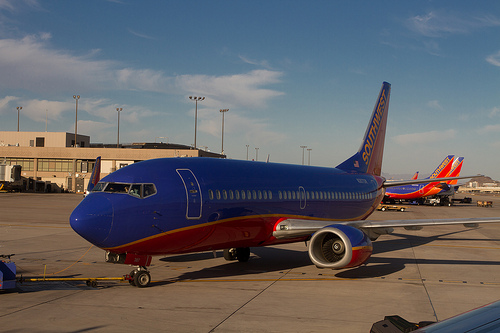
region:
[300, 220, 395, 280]
blue and red jet engine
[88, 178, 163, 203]
cockpit windows on front of plane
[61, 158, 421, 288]
blue and red airplane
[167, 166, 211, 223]
door on side of airplane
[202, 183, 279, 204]
windows on side of airplane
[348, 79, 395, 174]
company logo on airplane tail fin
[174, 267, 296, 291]
yellow stripes on airport runway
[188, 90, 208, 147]
large silver airport light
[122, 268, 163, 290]
landing wheels on airplane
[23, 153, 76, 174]
windows on side of building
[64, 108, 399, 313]
air plane is blue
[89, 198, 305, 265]
red trim of air plane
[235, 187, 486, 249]
silver wing of air plane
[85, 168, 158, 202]
window of air plane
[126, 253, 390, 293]
white line on pavement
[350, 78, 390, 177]
writing on tail of plane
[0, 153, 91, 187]
truck parked by building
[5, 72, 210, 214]
building in distance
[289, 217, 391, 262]
engine of airplane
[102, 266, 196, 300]
wheels of a plane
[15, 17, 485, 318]
An airplane waiting on tarmac.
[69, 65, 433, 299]
A red and blue airplane.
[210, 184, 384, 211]
Passenger windows on airplane.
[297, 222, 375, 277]
Left engine on airplane.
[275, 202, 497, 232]
Left wing on airplane.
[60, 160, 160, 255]
The nose of an airplane.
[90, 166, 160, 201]
The windshield on an airplane.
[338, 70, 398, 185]
The tail of an airplane.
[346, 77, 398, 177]
The word SOUTHWEST in gold letters.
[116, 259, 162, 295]
The front wheel of an airplane.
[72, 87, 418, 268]
blue and red plane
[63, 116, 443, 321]
a plane from southwest airlines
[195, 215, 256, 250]
red bottom of plane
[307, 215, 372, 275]
engine of the plane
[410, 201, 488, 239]
silver wing of plane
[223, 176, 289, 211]
windows on the plane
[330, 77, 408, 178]
tail of the plane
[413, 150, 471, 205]
two planes in background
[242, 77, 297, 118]
clouds in the sky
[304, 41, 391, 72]
blue sky above the land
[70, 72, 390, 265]
southwest plane at airport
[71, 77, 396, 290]
blue orange and red plane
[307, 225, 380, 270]
blue red and yellow engine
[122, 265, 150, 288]
black and white airplane wheels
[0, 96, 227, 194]
grey airport building in background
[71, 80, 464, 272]
three southwest planes near airport building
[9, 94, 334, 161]
tall lightposts at airport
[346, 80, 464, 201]
southwest airplane tails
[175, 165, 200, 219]
front door on airplane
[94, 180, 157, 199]
cockpit windows on airplane